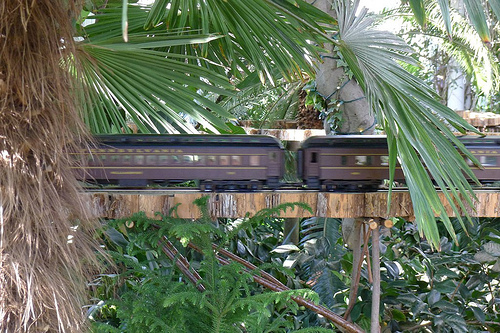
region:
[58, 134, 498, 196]
The train is brown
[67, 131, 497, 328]
Train is on the bridge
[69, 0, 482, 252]
Fan leaves are around train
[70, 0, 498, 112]
The sun is shining through leaves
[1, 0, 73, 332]
The tree is furry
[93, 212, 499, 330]
Several different types of leaves are shown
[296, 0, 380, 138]
Christmas lights are on tree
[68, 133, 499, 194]
Train is model toy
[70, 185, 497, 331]
Bridge is made of wood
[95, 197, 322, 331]
Plant in front is fern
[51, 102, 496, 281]
train on elevated track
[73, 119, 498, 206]
two passenger train cars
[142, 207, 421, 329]
train trestle support poles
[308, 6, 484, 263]
palm frond hanging in front of train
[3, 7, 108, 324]
brown shaggy tree trunk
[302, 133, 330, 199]
door to train car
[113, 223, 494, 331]
leafy green bushes below train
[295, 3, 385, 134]
string of lights around tree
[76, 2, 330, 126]
palm fronds hanging from tree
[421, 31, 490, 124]
tree with white trunk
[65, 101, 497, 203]
Train are blown and black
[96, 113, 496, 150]
Roof of train is black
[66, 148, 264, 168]
Windows of passenger trains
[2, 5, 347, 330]
Green leaves of tree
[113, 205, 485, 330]
Leaves below bridge of train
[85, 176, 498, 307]
Bridge under train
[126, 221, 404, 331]
Sticks that hold the bridge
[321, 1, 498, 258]
Leave of palm is extended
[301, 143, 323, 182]
Door of train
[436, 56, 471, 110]
White tube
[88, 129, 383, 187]
a brown toy train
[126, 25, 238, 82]
spiny leaves on a palm tree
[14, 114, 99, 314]
dead moss on a tree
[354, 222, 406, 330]
a metal support under the train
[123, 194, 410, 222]
a bamboo train track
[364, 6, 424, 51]
sunlight shining through the trees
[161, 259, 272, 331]
a green fern growing underneath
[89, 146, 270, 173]
window in the train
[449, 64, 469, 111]
a metal pole in the background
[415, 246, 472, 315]
leaves on a banana tree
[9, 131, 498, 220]
Moving train on tracks.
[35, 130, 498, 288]
Moving bridge on a bridge.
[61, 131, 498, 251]
Blue train moving on bridge railroad tracks.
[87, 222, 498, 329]
Trees with green leaves under the bridge.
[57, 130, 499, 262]
Blue train moving over a bridge rail tracks.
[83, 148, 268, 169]
Windows on the moving train.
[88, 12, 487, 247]
Long green leaves on a tree.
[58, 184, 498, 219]
Railroad tracks on the bridge.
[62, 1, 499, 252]
Large tree branch with green leaves over the moving train.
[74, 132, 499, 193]
Train with two cars moving on the tracks.